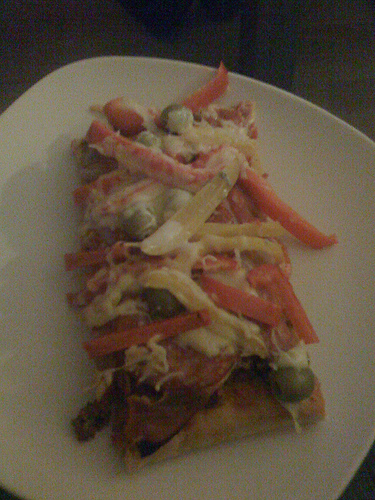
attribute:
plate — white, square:
[4, 60, 373, 499]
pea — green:
[274, 367, 314, 399]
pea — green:
[124, 209, 157, 243]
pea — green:
[163, 105, 193, 133]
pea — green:
[131, 127, 157, 152]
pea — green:
[149, 287, 177, 313]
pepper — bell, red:
[84, 122, 215, 194]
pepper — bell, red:
[241, 173, 331, 252]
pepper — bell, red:
[179, 61, 230, 113]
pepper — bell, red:
[260, 261, 314, 345]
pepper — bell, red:
[202, 276, 283, 328]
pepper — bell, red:
[87, 309, 210, 349]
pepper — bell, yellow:
[158, 156, 239, 257]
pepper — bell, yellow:
[136, 264, 254, 347]